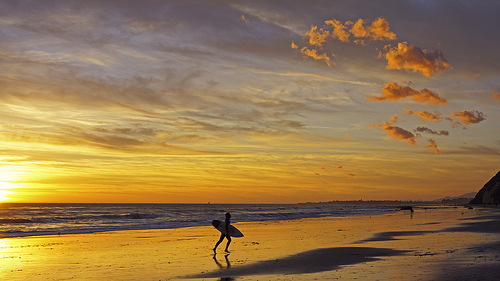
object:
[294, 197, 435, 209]
row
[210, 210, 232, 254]
person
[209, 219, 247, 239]
surf board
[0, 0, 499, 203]
sky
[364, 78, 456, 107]
clouds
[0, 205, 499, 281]
beach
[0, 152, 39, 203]
sun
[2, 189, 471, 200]
down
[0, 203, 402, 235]
ocean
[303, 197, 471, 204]
trees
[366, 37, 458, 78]
cloud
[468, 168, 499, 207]
hill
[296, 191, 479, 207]
distance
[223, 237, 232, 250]
leg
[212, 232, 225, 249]
leg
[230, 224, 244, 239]
pointy edge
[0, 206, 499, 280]
sand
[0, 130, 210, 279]
light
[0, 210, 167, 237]
wave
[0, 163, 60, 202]
corona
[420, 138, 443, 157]
cloud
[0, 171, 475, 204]
horizon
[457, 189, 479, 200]
hill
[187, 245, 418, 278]
shadowed